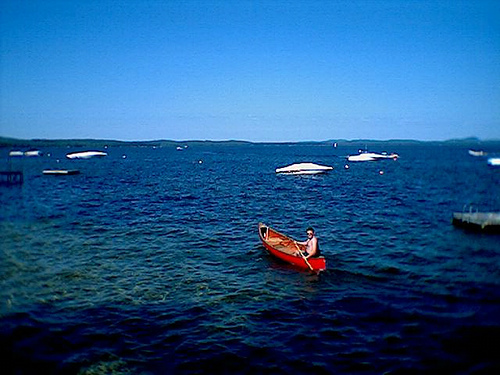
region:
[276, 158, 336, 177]
White boat on the water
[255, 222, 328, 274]
Red canoe on the water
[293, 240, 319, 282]
Man holding a paddle with both hands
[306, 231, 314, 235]
Man wearing sun glasses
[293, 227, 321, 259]
Man with no shirt in a canoe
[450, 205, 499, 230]
Wooden pier in the water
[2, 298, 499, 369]
Dark shadows in the water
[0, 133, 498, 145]
Land behind water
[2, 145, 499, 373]
boats out in the water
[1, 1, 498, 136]
Blue sky over water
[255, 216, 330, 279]
man in a boat on the water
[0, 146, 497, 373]
dark blue body of water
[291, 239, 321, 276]
long narrow wood paddle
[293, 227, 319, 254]
shirtless man in a boat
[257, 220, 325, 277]
bright red canoe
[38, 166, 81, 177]
square flat dock in the middle of the water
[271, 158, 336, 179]
white covered boat on the water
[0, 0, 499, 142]
brilliant blue sky above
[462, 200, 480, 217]
silver handles to a ladder on a dock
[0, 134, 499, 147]
barely visible distant shore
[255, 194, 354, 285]
this is a boat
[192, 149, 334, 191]
the boat is white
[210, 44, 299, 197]
there are no clouds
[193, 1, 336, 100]
the clouds are nonexistent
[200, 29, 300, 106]
the sky is clear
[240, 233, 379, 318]
the boat is red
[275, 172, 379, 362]
this is a canoe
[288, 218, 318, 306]
this is an oar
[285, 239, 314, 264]
this is a man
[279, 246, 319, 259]
this is a bathing suit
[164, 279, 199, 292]
blue waters in the ocean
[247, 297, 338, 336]
choppy waters in the sea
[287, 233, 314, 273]
oar in man's hand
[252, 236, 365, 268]
boat in the water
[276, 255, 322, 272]
red color on the boat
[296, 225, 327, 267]
man in red boat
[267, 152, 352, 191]
sleek large white boat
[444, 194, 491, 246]
dock in the water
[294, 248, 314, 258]
man wearing black shorts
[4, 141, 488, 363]
water with boats in it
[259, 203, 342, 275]
person in red boat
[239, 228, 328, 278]
red boat in the water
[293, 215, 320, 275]
person in red boat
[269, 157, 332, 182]
boat behind red boat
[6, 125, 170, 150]
land in the distance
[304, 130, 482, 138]
land in the distance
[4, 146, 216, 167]
boats further out in water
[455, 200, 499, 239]
structure near the water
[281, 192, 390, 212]
waves in the water